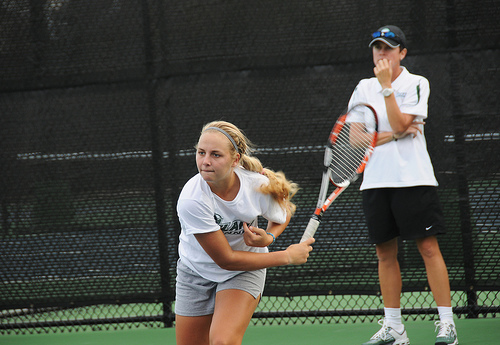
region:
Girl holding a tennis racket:
[295, 67, 392, 274]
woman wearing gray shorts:
[167, 245, 273, 322]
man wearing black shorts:
[353, 175, 449, 256]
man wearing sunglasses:
[361, 25, 408, 42]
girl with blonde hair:
[193, 127, 297, 199]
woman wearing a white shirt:
[161, 164, 288, 259]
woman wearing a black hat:
[360, 22, 404, 60]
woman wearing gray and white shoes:
[348, 308, 477, 344]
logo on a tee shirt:
[206, 208, 258, 248]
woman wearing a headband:
[181, 118, 240, 156]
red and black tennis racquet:
[298, 104, 376, 249]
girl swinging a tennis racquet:
[173, 103, 378, 344]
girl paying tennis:
[173, 102, 378, 344]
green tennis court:
[0, 294, 497, 343]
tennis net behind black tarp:
[10, 131, 495, 236]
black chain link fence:
[0, 2, 497, 337]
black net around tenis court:
[3, 0, 498, 310]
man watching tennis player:
[345, 24, 460, 344]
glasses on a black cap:
[367, 22, 408, 52]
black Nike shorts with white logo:
[359, 185, 449, 247]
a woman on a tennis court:
[152, 89, 494, 309]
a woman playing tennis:
[139, 139, 324, 343]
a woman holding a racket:
[134, 97, 407, 342]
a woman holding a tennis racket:
[137, 92, 354, 307]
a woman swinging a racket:
[175, 139, 392, 335]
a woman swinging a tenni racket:
[169, 106, 404, 341]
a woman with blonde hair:
[187, 103, 348, 325]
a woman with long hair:
[164, 81, 352, 341]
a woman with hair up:
[103, 49, 346, 337]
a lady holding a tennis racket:
[178, 117, 376, 343]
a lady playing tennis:
[164, 108, 357, 335]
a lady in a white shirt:
[166, 125, 314, 333]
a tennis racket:
[306, 105, 381, 251]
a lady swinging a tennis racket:
[176, 113, 397, 341]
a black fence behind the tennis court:
[0, 3, 470, 320]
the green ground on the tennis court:
[49, 318, 499, 342]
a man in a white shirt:
[329, 29, 460, 341]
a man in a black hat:
[348, 25, 454, 341]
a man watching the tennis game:
[350, 23, 457, 340]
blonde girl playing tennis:
[166, 98, 385, 342]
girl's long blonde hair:
[193, 108, 308, 224]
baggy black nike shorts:
[347, 168, 453, 252]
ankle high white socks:
[374, 297, 459, 328]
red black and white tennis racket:
[291, 98, 381, 253]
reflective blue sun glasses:
[367, 28, 399, 38]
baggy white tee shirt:
[170, 171, 292, 287]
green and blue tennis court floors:
[3, 171, 498, 343]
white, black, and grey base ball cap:
[363, 19, 413, 53]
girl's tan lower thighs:
[157, 279, 270, 341]